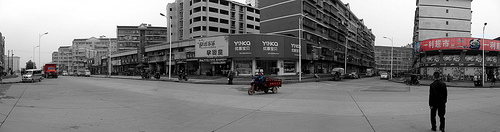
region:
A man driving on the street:
[249, 66, 282, 96]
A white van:
[21, 67, 41, 82]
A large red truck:
[43, 62, 58, 79]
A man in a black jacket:
[428, 69, 450, 130]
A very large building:
[413, 0, 469, 40]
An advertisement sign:
[196, 35, 308, 59]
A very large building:
[263, 0, 378, 70]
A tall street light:
[35, 30, 50, 71]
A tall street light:
[158, 12, 171, 79]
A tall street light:
[296, 12, 311, 79]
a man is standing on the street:
[402, 62, 472, 119]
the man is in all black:
[415, 65, 465, 124]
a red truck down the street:
[38, 53, 70, 87]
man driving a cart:
[224, 60, 299, 103]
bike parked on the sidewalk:
[166, 62, 198, 84]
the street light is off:
[140, 0, 175, 81]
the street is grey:
[100, 89, 330, 129]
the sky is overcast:
[1, 17, 107, 69]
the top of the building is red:
[419, 31, 495, 57]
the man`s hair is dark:
[428, 69, 443, 81]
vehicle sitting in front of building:
[192, 28, 363, 115]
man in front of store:
[394, 20, 476, 130]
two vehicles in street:
[1, 41, 102, 120]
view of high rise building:
[155, 4, 263, 92]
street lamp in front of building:
[356, 28, 416, 92]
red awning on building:
[378, 14, 498, 65]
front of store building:
[166, 12, 316, 113]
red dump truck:
[27, 50, 82, 102]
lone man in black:
[421, 56, 451, 130]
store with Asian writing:
[216, 27, 314, 63]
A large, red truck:
[43, 61, 58, 78]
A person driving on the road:
[248, 70, 284, 93]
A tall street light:
[478, 20, 488, 86]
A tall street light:
[384, 33, 395, 76]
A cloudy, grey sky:
[1, 3, 498, 68]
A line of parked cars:
[61, 68, 89, 76]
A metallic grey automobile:
[22, 65, 44, 82]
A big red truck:
[43, 62, 60, 79]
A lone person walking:
[427, 68, 449, 130]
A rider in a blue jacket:
[246, 70, 283, 95]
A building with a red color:
[432, 36, 467, 49]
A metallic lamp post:
[166, 10, 173, 80]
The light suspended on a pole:
[158, 10, 165, 19]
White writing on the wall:
[234, 38, 251, 46]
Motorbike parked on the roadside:
[174, 67, 189, 82]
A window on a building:
[445, 18, 450, 25]